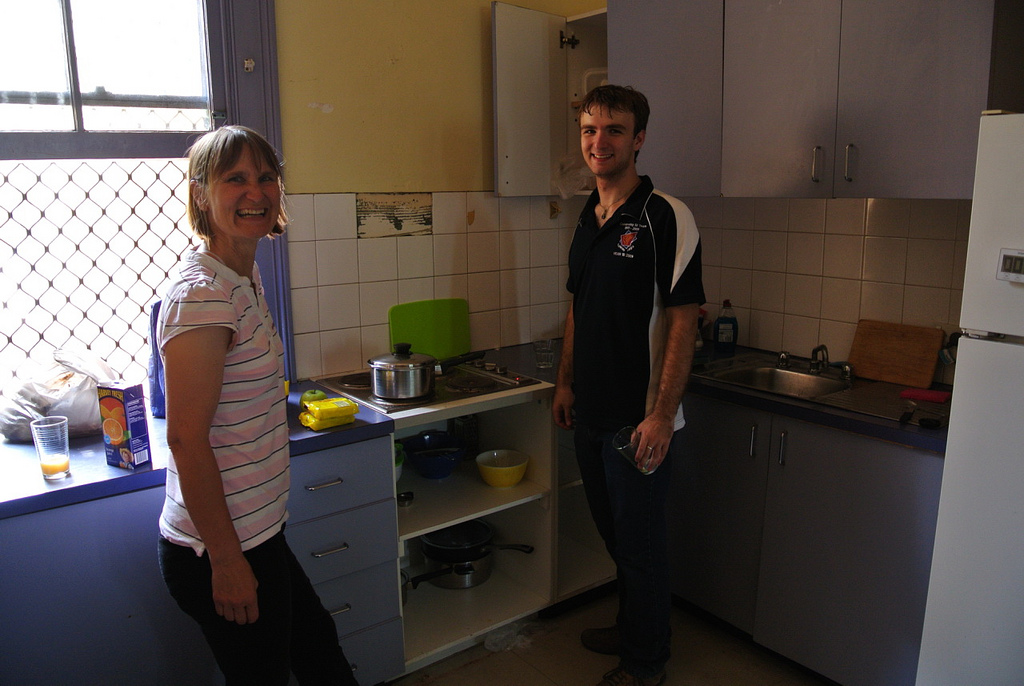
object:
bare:
[354, 193, 433, 237]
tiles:
[337, 243, 391, 293]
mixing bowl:
[477, 449, 531, 488]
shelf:
[408, 485, 465, 633]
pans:
[429, 532, 506, 586]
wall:
[970, 319, 992, 372]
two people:
[150, 85, 706, 686]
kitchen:
[0, 0, 1024, 675]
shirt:
[139, 258, 293, 544]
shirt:
[558, 172, 709, 436]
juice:
[39, 455, 69, 475]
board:
[848, 318, 944, 388]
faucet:
[810, 343, 829, 371]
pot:
[402, 431, 463, 478]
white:
[165, 540, 222, 601]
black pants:
[156, 531, 358, 684]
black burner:
[365, 342, 497, 399]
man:
[555, 83, 698, 686]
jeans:
[584, 414, 690, 685]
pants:
[153, 529, 296, 686]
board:
[388, 298, 470, 359]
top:
[0, 490, 112, 584]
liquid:
[777, 365, 812, 380]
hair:
[194, 135, 214, 234]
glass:
[614, 425, 660, 475]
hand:
[633, 409, 672, 466]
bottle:
[714, 297, 739, 355]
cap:
[722, 297, 731, 302]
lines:
[228, 320, 278, 373]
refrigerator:
[914, 106, 1020, 679]